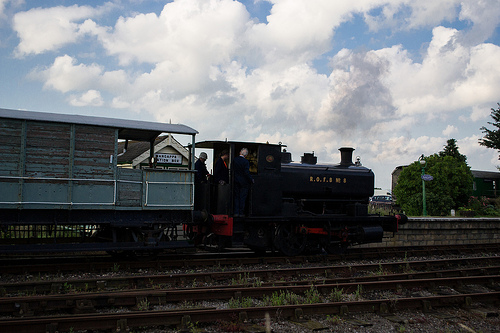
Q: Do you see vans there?
A: No, there are no vans.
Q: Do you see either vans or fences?
A: No, there are no vans or fences.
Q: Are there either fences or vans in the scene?
A: No, there are no vans or fences.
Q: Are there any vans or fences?
A: No, there are no vans or fences.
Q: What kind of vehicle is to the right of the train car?
A: The vehicle is a locomotive.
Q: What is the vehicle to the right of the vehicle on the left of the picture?
A: The vehicle is a locomotive.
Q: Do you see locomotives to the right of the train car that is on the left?
A: Yes, there is a locomotive to the right of the train car.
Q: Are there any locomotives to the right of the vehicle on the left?
A: Yes, there is a locomotive to the right of the train car.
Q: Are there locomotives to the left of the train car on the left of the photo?
A: No, the locomotive is to the right of the train car.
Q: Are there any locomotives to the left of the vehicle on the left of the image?
A: No, the locomotive is to the right of the train car.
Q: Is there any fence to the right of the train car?
A: No, there is a locomotive to the right of the train car.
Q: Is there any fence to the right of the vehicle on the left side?
A: No, there is a locomotive to the right of the train car.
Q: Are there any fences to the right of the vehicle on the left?
A: No, there is a locomotive to the right of the train car.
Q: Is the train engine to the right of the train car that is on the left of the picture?
A: Yes, the train engine is to the right of the train car.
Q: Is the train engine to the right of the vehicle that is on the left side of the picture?
A: Yes, the train engine is to the right of the train car.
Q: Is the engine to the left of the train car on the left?
A: No, the engine is to the right of the train car.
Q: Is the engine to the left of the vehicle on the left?
A: No, the engine is to the right of the train car.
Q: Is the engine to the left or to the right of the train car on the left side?
A: The engine is to the right of the train car.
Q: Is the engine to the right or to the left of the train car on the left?
A: The engine is to the right of the train car.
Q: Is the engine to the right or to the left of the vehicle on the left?
A: The engine is to the right of the train car.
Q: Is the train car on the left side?
A: Yes, the train car is on the left of the image.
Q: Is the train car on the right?
A: No, the train car is on the left of the image.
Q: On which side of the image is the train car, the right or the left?
A: The train car is on the left of the image.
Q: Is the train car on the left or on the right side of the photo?
A: The train car is on the left of the image.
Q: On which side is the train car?
A: The train car is on the left of the image.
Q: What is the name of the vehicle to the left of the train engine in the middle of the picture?
A: The vehicle is a train car.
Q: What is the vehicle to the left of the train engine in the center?
A: The vehicle is a train car.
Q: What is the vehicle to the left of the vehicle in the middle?
A: The vehicle is a train car.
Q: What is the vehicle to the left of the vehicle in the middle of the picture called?
A: The vehicle is a train car.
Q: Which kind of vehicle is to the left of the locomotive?
A: The vehicle is a train car.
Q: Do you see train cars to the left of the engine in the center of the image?
A: Yes, there is a train car to the left of the train engine.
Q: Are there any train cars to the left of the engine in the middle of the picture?
A: Yes, there is a train car to the left of the train engine.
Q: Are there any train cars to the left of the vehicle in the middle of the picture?
A: Yes, there is a train car to the left of the train engine.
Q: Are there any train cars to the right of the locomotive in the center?
A: No, the train car is to the left of the locomotive.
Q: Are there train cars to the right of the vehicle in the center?
A: No, the train car is to the left of the locomotive.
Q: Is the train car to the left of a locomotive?
A: Yes, the train car is to the left of a locomotive.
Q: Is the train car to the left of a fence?
A: No, the train car is to the left of a locomotive.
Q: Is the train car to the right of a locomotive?
A: No, the train car is to the left of a locomotive.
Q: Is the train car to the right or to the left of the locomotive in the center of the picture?
A: The train car is to the left of the train engine.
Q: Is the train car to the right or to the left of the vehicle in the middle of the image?
A: The train car is to the left of the train engine.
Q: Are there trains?
A: Yes, there is a train.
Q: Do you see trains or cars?
A: Yes, there is a train.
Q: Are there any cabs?
A: No, there are no cabs.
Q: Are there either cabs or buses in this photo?
A: No, there are no cabs or buses.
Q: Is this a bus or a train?
A: This is a train.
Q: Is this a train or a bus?
A: This is a train.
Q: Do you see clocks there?
A: No, there are no clocks.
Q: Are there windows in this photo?
A: Yes, there is a window.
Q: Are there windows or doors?
A: Yes, there is a window.